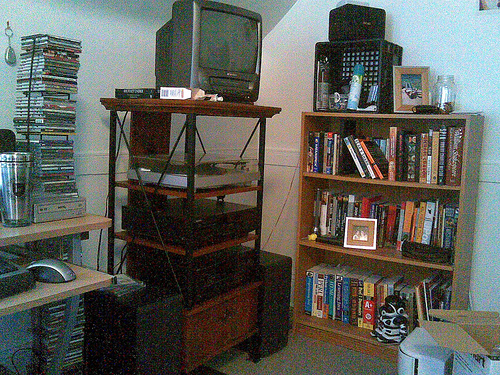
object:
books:
[314, 271, 325, 320]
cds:
[18, 33, 83, 41]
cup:
[0, 150, 33, 228]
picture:
[344, 217, 378, 251]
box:
[414, 305, 497, 375]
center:
[74, 46, 324, 355]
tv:
[154, 1, 261, 106]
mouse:
[22, 257, 77, 284]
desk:
[3, 212, 114, 368]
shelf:
[299, 237, 453, 271]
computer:
[0, 250, 79, 302]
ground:
[217, 335, 392, 374]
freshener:
[346, 64, 365, 108]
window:
[475, 2, 498, 13]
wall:
[257, 3, 500, 310]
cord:
[94, 197, 107, 268]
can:
[343, 64, 366, 112]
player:
[126, 165, 261, 190]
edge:
[85, 210, 112, 220]